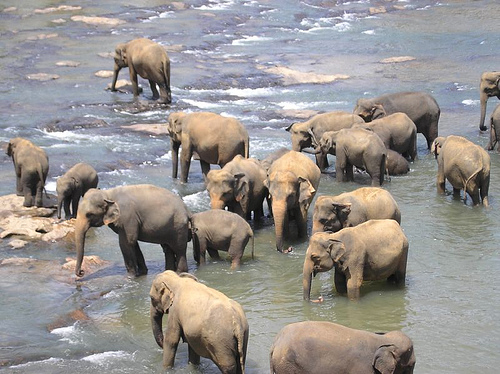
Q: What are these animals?
A: Elephants.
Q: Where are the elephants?
A: In the water.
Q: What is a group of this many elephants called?
A: A herd.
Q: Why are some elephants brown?
A: Mud.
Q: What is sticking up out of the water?
A: Rocks.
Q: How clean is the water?
A: Dirty.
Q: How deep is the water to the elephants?
A: Knee deep.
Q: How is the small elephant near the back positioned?
A: Sitting.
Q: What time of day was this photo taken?
A: It was taken during the day.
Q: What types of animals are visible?
A: Elephants.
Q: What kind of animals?
A: Elephants.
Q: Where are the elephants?
A: In the water.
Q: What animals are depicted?
A: Elephants.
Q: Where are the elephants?
A: In the water.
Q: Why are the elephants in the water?
A: To drink.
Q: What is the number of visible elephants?
A: 17.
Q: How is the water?
A: Shallow and murky.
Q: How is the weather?
A: Sunny.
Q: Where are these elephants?
A: In the wild.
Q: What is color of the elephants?
A: Gray.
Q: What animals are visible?
A: Elephants.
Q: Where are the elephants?
A: In the water.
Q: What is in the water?
A: Rocks.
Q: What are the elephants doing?
A: Wading.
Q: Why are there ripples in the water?
A: From the rocks.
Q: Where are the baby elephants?
A: Next to their mothers.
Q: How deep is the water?
A: Not deep.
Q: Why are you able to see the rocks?
A: Shallow water.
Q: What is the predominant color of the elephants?
A: Grey.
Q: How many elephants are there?
A: 20.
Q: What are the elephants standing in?
A: Water.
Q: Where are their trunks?
A: In the water.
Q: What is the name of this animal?
A: Elephant.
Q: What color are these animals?
A: Gray.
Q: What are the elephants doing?
A: Bathing.